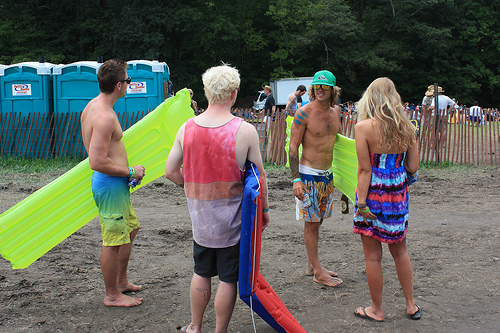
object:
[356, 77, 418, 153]
hair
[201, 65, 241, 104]
hair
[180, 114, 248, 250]
tank top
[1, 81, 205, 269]
float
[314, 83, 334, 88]
goggles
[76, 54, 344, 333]
man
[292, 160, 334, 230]
shorts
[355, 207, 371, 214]
bracelet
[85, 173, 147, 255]
shorts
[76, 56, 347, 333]
guy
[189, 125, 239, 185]
section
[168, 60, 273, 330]
guy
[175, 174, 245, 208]
section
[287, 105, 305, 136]
stripes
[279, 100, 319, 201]
arm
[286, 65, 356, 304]
guy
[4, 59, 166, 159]
potties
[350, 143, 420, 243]
dress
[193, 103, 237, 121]
neck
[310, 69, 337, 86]
cap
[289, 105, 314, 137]
paint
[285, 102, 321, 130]
shoulder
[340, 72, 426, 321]
girl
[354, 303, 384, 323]
foot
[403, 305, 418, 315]
foot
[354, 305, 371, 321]
sandal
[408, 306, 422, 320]
sandal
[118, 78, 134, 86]
glasses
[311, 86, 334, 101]
head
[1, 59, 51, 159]
bathroom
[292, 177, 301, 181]
bracelet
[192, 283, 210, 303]
tattoo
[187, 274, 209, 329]
leg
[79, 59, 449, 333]
person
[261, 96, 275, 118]
shirt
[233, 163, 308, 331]
raft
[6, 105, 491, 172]
fence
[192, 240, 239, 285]
shorts